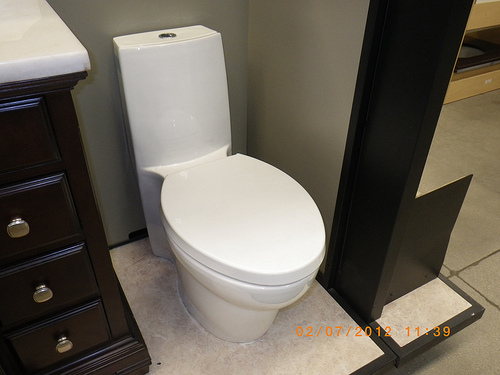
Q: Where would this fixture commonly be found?
A: Restroom.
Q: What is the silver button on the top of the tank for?
A: To flush.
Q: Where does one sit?
A: Toilet seat.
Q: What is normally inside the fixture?
A: Water.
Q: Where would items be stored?
A: Drawers.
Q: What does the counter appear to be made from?
A: Marble.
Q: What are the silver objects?
A: Drawer handles.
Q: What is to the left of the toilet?
A: Sink and cabinet.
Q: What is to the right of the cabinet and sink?
A: Toilet.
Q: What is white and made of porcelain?
A: A toilet.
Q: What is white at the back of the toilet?
A: A reservoir.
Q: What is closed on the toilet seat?
A: The lid.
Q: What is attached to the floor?
A: The white toilet bowl base.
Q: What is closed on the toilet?
A: A white lid.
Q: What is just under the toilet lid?
A: A white bowl.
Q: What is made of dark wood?
A: A set of drawers.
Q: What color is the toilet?
A: White.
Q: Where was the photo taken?
A: Washroom.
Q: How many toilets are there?
A: One.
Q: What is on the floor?
A: Tiles.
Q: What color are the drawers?
A: Dark brown.